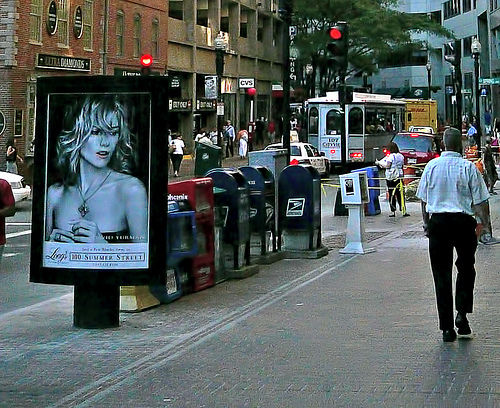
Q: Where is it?
A: This is at the road.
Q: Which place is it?
A: It is a road.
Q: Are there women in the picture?
A: Yes, there is a woman.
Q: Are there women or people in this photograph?
A: Yes, there is a woman.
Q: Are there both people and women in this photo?
A: Yes, there are both a woman and a person.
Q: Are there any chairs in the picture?
A: No, there are no chairs.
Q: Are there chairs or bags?
A: No, there are no chairs or bags.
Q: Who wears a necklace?
A: The woman wears a necklace.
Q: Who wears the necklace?
A: The woman wears a necklace.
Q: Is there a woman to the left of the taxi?
A: Yes, there is a woman to the left of the taxi.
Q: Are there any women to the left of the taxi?
A: Yes, there is a woman to the left of the taxi.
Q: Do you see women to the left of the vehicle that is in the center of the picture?
A: Yes, there is a woman to the left of the taxi.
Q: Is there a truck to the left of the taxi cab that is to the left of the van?
A: No, there is a woman to the left of the taxi.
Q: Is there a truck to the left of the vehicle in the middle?
A: No, there is a woman to the left of the taxi.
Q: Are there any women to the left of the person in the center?
A: Yes, there is a woman to the left of the person.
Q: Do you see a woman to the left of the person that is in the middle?
A: Yes, there is a woman to the left of the person.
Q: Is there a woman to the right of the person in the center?
A: No, the woman is to the left of the person.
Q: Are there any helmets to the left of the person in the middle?
A: No, there is a woman to the left of the person.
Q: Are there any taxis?
A: Yes, there is a taxi.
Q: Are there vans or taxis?
A: Yes, there is a taxi.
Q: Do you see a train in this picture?
A: No, there are no trains.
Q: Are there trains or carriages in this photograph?
A: No, there are no trains or carriages.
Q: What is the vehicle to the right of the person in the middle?
A: The vehicle is a taxi.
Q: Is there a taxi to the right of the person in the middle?
A: Yes, there is a taxi to the right of the person.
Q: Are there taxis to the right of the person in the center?
A: Yes, there is a taxi to the right of the person.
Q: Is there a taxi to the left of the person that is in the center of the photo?
A: No, the taxi is to the right of the person.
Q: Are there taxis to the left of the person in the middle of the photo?
A: No, the taxi is to the right of the person.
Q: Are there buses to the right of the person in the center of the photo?
A: No, there is a taxi to the right of the person.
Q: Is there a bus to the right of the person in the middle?
A: No, there is a taxi to the right of the person.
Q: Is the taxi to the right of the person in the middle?
A: Yes, the taxi is to the right of the person.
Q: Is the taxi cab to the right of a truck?
A: No, the taxi cab is to the right of the person.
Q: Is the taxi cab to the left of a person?
A: No, the taxi cab is to the right of a person.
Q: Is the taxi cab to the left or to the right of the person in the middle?
A: The taxi cab is to the right of the person.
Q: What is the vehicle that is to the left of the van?
A: The vehicle is a taxi.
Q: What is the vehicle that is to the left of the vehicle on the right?
A: The vehicle is a taxi.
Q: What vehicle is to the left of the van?
A: The vehicle is a taxi.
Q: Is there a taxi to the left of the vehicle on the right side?
A: Yes, there is a taxi to the left of the van.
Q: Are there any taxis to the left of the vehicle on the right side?
A: Yes, there is a taxi to the left of the van.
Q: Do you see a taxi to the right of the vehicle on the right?
A: No, the taxi is to the left of the van.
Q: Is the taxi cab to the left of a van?
A: Yes, the taxi cab is to the left of a van.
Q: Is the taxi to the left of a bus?
A: No, the taxi is to the left of a van.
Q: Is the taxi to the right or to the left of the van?
A: The taxi is to the left of the van.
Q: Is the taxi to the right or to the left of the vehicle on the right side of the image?
A: The taxi is to the left of the van.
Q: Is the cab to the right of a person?
A: Yes, the cab is to the right of a person.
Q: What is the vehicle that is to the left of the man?
A: The vehicle is a taxi.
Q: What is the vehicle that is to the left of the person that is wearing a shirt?
A: The vehicle is a taxi.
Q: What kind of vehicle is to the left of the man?
A: The vehicle is a taxi.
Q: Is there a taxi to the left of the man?
A: Yes, there is a taxi to the left of the man.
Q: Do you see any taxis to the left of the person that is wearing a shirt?
A: Yes, there is a taxi to the left of the man.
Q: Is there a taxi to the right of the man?
A: No, the taxi is to the left of the man.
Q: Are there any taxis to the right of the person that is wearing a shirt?
A: No, the taxi is to the left of the man.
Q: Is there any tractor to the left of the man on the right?
A: No, there is a taxi to the left of the man.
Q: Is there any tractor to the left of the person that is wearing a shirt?
A: No, there is a taxi to the left of the man.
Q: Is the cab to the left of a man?
A: Yes, the cab is to the left of a man.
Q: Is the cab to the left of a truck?
A: No, the cab is to the left of a man.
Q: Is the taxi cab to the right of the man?
A: No, the taxi cab is to the left of the man.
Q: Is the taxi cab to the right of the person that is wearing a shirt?
A: No, the taxi cab is to the left of the man.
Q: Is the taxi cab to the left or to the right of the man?
A: The taxi cab is to the left of the man.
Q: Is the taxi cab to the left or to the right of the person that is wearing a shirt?
A: The taxi cab is to the left of the man.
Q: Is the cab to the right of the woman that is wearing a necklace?
A: Yes, the cab is to the right of the woman.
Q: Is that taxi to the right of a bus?
A: No, the taxi is to the right of the woman.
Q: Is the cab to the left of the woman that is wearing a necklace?
A: No, the cab is to the right of the woman.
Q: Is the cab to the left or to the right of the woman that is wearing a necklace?
A: The cab is to the right of the woman.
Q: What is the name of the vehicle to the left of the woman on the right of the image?
A: The vehicle is a taxi.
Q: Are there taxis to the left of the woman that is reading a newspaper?
A: Yes, there is a taxi to the left of the woman.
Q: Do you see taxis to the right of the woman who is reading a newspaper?
A: No, the taxi is to the left of the woman.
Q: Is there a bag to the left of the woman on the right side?
A: No, there is a taxi to the left of the woman.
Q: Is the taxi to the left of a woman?
A: Yes, the taxi is to the left of a woman.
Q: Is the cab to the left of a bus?
A: No, the cab is to the left of a woman.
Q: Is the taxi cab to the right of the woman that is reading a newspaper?
A: No, the taxi cab is to the left of the woman.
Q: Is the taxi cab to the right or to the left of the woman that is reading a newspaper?
A: The taxi cab is to the left of the woman.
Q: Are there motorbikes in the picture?
A: No, there are no motorbikes.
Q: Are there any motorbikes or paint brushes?
A: No, there are no motorbikes or paint brushes.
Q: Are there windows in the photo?
A: Yes, there are windows.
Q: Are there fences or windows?
A: Yes, there are windows.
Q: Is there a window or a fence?
A: Yes, there are windows.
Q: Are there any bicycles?
A: No, there are no bicycles.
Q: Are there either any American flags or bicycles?
A: No, there are no bicycles or American flags.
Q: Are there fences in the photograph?
A: No, there are no fences.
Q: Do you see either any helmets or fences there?
A: No, there are no fences or helmets.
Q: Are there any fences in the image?
A: No, there are no fences.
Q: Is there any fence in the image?
A: No, there are no fences.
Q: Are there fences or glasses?
A: No, there are no fences or glasses.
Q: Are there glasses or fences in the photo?
A: No, there are no fences or glasses.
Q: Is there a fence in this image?
A: No, there are no fences.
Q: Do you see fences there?
A: No, there are no fences.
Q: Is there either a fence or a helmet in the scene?
A: No, there are no fences or helmets.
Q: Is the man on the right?
A: Yes, the man is on the right of the image.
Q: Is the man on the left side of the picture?
A: No, the man is on the right of the image.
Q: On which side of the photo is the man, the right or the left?
A: The man is on the right of the image.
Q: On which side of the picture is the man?
A: The man is on the right of the image.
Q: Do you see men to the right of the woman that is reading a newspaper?
A: Yes, there is a man to the right of the woman.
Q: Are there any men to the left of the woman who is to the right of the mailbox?
A: No, the man is to the right of the woman.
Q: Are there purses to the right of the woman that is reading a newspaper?
A: No, there is a man to the right of the woman.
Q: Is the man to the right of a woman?
A: Yes, the man is to the right of a woman.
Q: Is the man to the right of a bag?
A: No, the man is to the right of a woman.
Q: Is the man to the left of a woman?
A: No, the man is to the right of a woman.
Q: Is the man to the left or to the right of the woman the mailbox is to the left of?
A: The man is to the right of the woman.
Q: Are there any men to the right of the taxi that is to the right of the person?
A: Yes, there is a man to the right of the taxi.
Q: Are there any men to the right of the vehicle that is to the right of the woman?
A: Yes, there is a man to the right of the taxi.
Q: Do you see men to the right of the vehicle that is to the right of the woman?
A: Yes, there is a man to the right of the taxi.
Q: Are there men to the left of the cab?
A: No, the man is to the right of the cab.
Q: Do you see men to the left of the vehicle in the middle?
A: No, the man is to the right of the cab.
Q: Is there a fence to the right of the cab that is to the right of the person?
A: No, there is a man to the right of the cab.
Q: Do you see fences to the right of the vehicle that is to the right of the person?
A: No, there is a man to the right of the cab.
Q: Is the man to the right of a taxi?
A: Yes, the man is to the right of a taxi.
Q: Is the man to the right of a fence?
A: No, the man is to the right of a taxi.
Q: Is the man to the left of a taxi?
A: No, the man is to the right of a taxi.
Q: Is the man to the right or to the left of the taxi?
A: The man is to the right of the taxi.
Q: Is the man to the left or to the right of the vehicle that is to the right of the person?
A: The man is to the right of the taxi.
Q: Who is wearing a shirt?
A: The man is wearing a shirt.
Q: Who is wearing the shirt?
A: The man is wearing a shirt.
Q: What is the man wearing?
A: The man is wearing a shirt.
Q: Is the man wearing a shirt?
A: Yes, the man is wearing a shirt.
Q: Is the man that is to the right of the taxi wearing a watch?
A: No, the man is wearing a shirt.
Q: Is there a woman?
A: Yes, there is a woman.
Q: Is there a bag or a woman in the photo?
A: Yes, there is a woman.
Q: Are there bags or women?
A: Yes, there is a woman.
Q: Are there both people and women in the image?
A: Yes, there are both a woman and a person.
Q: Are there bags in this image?
A: No, there are no bags.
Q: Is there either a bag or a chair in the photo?
A: No, there are no bags or chairs.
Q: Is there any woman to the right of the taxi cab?
A: Yes, there is a woman to the right of the taxi cab.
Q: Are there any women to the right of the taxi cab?
A: Yes, there is a woman to the right of the taxi cab.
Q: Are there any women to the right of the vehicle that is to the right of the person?
A: Yes, there is a woman to the right of the taxi cab.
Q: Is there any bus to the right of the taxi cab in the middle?
A: No, there is a woman to the right of the taxi cab.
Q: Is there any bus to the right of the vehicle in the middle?
A: No, there is a woman to the right of the taxi cab.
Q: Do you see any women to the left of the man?
A: Yes, there is a woman to the left of the man.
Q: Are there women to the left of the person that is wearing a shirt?
A: Yes, there is a woman to the left of the man.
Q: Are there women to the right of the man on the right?
A: No, the woman is to the left of the man.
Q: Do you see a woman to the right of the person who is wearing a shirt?
A: No, the woman is to the left of the man.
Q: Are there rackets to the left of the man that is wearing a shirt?
A: No, there is a woman to the left of the man.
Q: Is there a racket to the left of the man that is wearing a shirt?
A: No, there is a woman to the left of the man.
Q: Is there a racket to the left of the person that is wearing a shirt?
A: No, there is a woman to the left of the man.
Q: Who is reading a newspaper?
A: The woman is reading a newspaper.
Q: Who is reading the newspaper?
A: The woman is reading a newspaper.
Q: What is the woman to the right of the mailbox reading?
A: The woman is reading a newspaper.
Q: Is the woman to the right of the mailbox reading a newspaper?
A: Yes, the woman is reading a newspaper.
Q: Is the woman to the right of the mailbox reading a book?
A: No, the woman is reading a newspaper.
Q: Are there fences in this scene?
A: No, there are no fences.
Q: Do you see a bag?
A: No, there are no bags.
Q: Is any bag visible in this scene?
A: No, there are no bags.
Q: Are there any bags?
A: No, there are no bags.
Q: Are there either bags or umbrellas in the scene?
A: No, there are no bags or umbrellas.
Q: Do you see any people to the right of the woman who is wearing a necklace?
A: Yes, there are people to the right of the woman.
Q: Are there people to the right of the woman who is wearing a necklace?
A: Yes, there are people to the right of the woman.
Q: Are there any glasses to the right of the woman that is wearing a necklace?
A: No, there are people to the right of the woman.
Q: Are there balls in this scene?
A: No, there are no balls.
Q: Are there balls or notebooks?
A: No, there are no balls or notebooks.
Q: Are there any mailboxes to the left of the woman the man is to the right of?
A: Yes, there is a mailbox to the left of the woman.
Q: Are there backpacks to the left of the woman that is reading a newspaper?
A: No, there is a mailbox to the left of the woman.